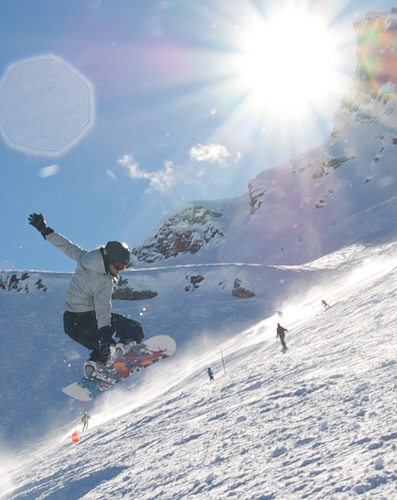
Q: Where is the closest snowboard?
A: In the air.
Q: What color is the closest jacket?
A: White.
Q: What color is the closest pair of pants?
A: Black.